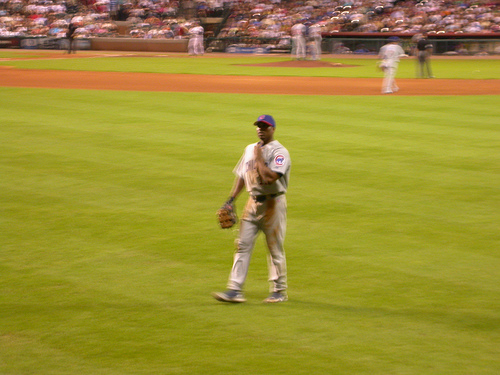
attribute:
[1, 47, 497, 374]
field — baseball, part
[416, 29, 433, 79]
umpire — baseball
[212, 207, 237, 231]
gloves — baseball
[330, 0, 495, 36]
public — out of focus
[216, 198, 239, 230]
mitt — leather, catcher's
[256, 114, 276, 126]
cap — blue 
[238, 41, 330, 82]
mound — pitcher's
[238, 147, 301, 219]
uniform — white, striped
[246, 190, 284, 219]
buckle — silver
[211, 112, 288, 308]
player — baseball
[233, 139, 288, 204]
shirt — white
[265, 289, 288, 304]
shoe — white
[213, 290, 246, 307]
shoe — white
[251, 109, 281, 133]
cap — baseball, blue, red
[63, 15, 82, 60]
man — black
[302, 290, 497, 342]
shadow — black 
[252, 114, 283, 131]
hat — blue, red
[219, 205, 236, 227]
mitt — brown, leather, baseball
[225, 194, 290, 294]
pants — dirty, white 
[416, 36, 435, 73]
clothes — black, gray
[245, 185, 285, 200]
belt — black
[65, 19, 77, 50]
clothes — black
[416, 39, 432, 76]
clothes — black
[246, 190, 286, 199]
belt — black, leather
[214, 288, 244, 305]
sneaker — out of focus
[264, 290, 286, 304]
sneaker — out of focus